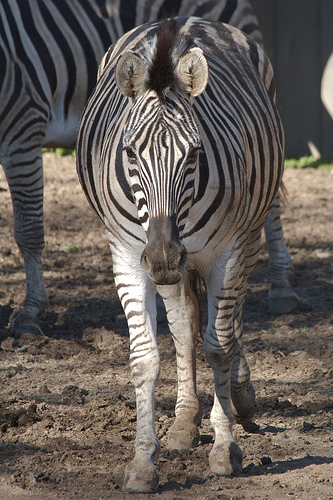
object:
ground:
[0, 337, 120, 499]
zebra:
[75, 17, 290, 469]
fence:
[286, 0, 333, 163]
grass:
[293, 148, 317, 174]